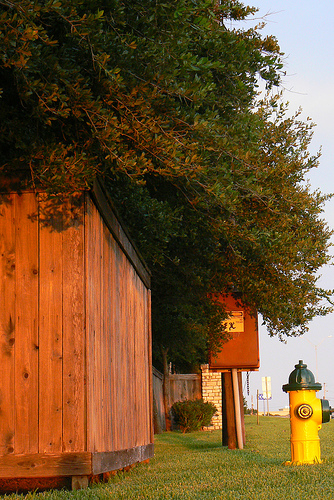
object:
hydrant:
[285, 355, 325, 473]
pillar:
[205, 366, 217, 400]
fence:
[93, 226, 117, 434]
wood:
[45, 385, 61, 410]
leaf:
[269, 216, 281, 221]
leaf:
[50, 95, 64, 100]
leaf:
[172, 6, 195, 16]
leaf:
[188, 58, 199, 68]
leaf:
[161, 226, 167, 231]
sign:
[258, 391, 263, 402]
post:
[226, 385, 232, 447]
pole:
[234, 390, 247, 448]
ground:
[178, 440, 207, 457]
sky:
[289, 14, 323, 69]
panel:
[72, 243, 82, 436]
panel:
[24, 210, 35, 470]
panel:
[140, 292, 152, 440]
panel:
[126, 287, 134, 445]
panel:
[5, 218, 10, 476]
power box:
[229, 310, 248, 363]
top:
[294, 364, 312, 385]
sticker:
[236, 315, 242, 329]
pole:
[322, 380, 325, 397]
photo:
[1, 1, 332, 495]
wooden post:
[229, 369, 245, 452]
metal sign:
[206, 281, 259, 371]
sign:
[209, 293, 257, 445]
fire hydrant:
[281, 358, 333, 465]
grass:
[4, 415, 329, 498]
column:
[198, 359, 225, 431]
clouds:
[249, 71, 326, 124]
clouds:
[277, 138, 333, 217]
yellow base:
[281, 389, 321, 465]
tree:
[17, 7, 255, 202]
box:
[201, 278, 260, 372]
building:
[1, 161, 157, 487]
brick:
[195, 362, 247, 430]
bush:
[169, 398, 211, 433]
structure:
[198, 357, 231, 433]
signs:
[258, 379, 270, 399]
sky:
[230, 18, 326, 440]